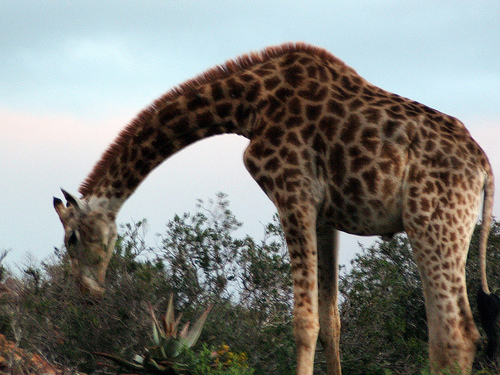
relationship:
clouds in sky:
[0, 0, 498, 301] [0, 0, 498, 307]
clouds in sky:
[0, 0, 498, 301] [3, 5, 495, 182]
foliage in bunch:
[1, 190, 499, 374] [139, 292, 211, 367]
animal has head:
[41, 28, 499, 369] [53, 189, 117, 299]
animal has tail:
[41, 28, 499, 369] [458, 153, 497, 313]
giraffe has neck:
[55, 41, 494, 373] [107, 74, 241, 209]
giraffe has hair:
[55, 41, 494, 373] [93, 64, 267, 178]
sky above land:
[0, 0, 498, 307] [2, 253, 496, 373]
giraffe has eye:
[55, 41, 494, 373] [62, 232, 104, 254]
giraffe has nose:
[55, 41, 494, 373] [74, 272, 109, 309]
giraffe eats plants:
[55, 41, 494, 373] [33, 240, 282, 370]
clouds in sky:
[0, 0, 498, 301] [33, 14, 428, 172]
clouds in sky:
[0, 0, 498, 301] [57, 9, 197, 59]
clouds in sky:
[0, 0, 498, 301] [6, 4, 496, 136]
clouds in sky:
[0, 0, 498, 301] [1, 2, 499, 200]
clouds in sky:
[0, 0, 498, 301] [368, 33, 439, 77]